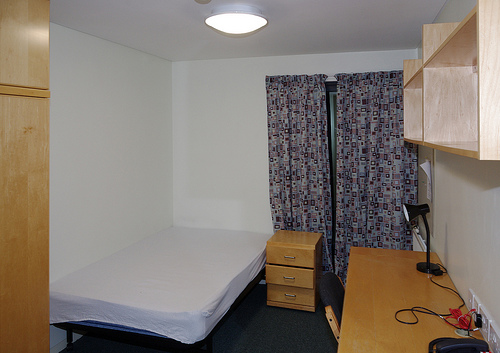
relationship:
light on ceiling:
[200, 4, 270, 41] [53, 2, 443, 61]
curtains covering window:
[269, 77, 416, 287] [251, 71, 440, 283]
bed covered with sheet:
[51, 222, 273, 351] [149, 217, 201, 324]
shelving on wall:
[391, 1, 498, 161] [399, 17, 498, 348]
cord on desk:
[444, 300, 481, 333] [326, 244, 491, 351]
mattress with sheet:
[48, 227, 273, 348] [48, 227, 270, 343]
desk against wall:
[326, 244, 491, 351] [416, 1, 493, 351]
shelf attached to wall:
[418, 10, 495, 160] [440, 163, 498, 255]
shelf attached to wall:
[400, 0, 499, 160] [440, 163, 498, 255]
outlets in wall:
[470, 300, 496, 343] [448, 202, 499, 288]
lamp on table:
[377, 192, 449, 296] [340, 239, 491, 351]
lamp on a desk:
[403, 203, 441, 274] [326, 244, 491, 351]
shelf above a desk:
[400, 0, 499, 160] [326, 244, 491, 351]